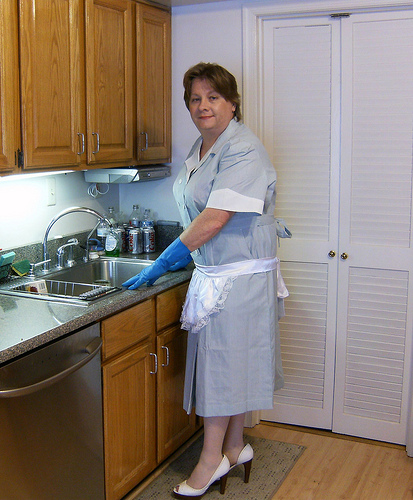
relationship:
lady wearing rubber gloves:
[120, 62, 293, 500] [121, 234, 192, 290]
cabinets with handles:
[11, 8, 173, 159] [76, 128, 104, 157]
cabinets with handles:
[106, 325, 180, 491] [145, 341, 172, 377]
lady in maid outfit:
[120, 62, 293, 500] [169, 118, 294, 419]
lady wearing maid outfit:
[120, 62, 293, 500] [169, 118, 294, 419]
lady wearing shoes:
[120, 62, 293, 500] [171, 440, 257, 497]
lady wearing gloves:
[120, 62, 293, 500] [125, 245, 182, 289]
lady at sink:
[120, 62, 293, 500] [60, 241, 170, 289]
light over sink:
[1, 167, 75, 181] [2, 250, 160, 307]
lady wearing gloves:
[120, 62, 293, 500] [83, 232, 225, 313]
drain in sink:
[5, 273, 119, 304] [2, 250, 160, 307]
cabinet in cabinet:
[0, 321, 106, 500] [0, 297, 101, 498]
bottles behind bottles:
[104, 222, 156, 257] [104, 222, 156, 257]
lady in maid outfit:
[120, 62, 293, 500] [169, 125, 272, 484]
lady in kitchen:
[120, 62, 293, 500] [6, 26, 395, 498]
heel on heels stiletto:
[213, 470, 229, 498] [172, 441, 253, 500]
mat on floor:
[131, 426, 305, 496] [125, 409, 411, 496]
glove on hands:
[123, 234, 188, 291] [121, 262, 159, 291]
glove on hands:
[121, 236, 194, 291] [167, 252, 190, 269]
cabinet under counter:
[0, 321, 106, 500] [1, 230, 215, 359]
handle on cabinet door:
[140, 347, 160, 379] [103, 342, 154, 495]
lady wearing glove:
[120, 62, 293, 500] [164, 253, 194, 277]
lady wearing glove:
[120, 62, 293, 500] [122, 235, 190, 295]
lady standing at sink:
[117, 57, 285, 498] [0, 203, 175, 310]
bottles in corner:
[104, 222, 156, 257] [92, 180, 154, 250]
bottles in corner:
[101, 204, 161, 251] [92, 180, 154, 250]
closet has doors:
[268, 18, 411, 441] [337, 17, 411, 446]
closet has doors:
[268, 18, 411, 441] [265, 15, 333, 420]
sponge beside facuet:
[9, 259, 32, 276] [42, 205, 112, 272]